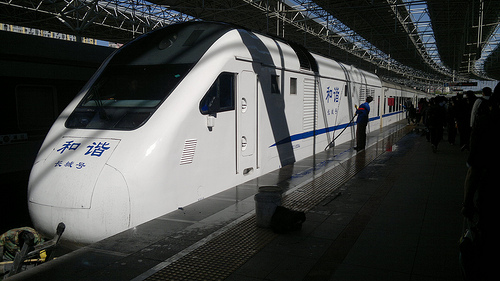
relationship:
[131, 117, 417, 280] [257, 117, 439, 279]
line painted on ground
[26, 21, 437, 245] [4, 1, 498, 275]
car stopped in station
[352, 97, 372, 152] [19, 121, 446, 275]
person standing on ground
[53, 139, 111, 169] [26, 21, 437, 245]
writing on front of car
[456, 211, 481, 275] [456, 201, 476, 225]
bag held in hand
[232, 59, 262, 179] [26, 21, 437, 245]
door on side of car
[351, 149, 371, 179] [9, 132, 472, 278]
reflection visible on ground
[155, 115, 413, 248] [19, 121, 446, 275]
water visible on ground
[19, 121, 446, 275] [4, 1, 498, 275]
ground inside station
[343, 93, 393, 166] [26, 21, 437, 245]
man participates in washing car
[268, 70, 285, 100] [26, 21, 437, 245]
window on car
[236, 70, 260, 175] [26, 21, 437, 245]
door on car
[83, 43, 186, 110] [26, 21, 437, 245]
window on car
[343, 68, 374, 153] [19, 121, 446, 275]
pedestrians on ground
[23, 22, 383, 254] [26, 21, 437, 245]
car on car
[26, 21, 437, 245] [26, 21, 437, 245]
car on car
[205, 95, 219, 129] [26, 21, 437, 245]
mirror on car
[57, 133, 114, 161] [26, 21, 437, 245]
symbols on car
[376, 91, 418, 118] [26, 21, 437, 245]
windows on car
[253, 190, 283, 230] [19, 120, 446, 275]
bucket on ground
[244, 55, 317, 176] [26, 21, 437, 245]
shadow on car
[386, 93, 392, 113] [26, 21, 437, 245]
window on car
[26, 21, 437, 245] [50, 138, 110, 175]
car has writing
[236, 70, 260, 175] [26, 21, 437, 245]
door to car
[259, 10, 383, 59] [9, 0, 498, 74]
lights stripe ceiling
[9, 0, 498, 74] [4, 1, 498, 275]
ceiling of station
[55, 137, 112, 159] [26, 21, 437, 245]
writing on car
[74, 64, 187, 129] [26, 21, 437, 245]
window on car